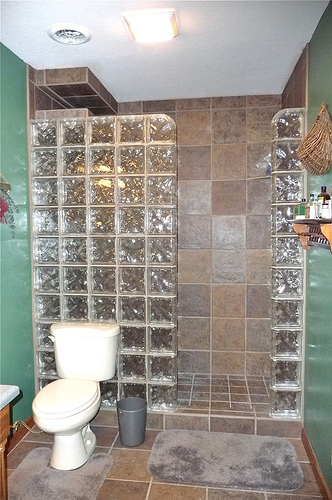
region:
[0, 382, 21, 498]
An edge of a wood framed granite topped bathroom sink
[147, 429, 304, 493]
A gray area rug used as a shower mat on the tiled floor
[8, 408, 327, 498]
Brown tiled bathroom floor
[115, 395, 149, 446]
Round green plastic garbage can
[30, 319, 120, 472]
White ceramic toilet against shower wall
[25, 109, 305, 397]
Glass block shower wall.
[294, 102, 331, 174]
Brown, woven wicker holder basket on right wall.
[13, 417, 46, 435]
Toilet water connection braided metal hose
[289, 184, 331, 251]
Wooden shelf on right wall loaded with toiletries.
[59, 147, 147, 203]
A yellow glow can be seen reflecting from or showing through the glass brick shower wall.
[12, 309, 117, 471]
White color western toilet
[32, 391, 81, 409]
Lid of the western toilet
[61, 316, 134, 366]
White color tank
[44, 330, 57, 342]
Handle of the tank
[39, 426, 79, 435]
Toilet bowl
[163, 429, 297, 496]
Grey color floor mate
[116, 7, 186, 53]
Ceiling light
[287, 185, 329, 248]
Wooden rack attached with wall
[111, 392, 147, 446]
Grey color dustbin near the western toilet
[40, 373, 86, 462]
this is a toilet sink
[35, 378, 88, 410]
this is the lid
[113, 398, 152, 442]
this is a container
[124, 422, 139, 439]
the container is made of plastic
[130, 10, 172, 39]
this is a light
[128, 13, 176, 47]
the light is on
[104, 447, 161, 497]
this is the floor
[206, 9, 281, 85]
this is the roof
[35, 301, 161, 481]
a bathroom toilet inside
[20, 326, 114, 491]
a bathroom toilet that is white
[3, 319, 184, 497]
a white toilet in the bathroom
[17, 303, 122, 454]
a toilet with lid down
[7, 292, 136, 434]
a toilet with seat down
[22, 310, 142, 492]
a white toilet with seat down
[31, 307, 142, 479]
a white toilet with lid down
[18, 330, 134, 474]
a bathroom toilet with white toilet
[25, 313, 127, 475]
A white porcelain toilet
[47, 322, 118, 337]
shiny white toilet tank lid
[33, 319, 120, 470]
clean white porcelain toilet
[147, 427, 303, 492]
fluffy grey bathroom rug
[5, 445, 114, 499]
fluffy grey toilet rug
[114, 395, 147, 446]
empty silver metal trashcan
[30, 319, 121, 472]
toilet in front of glass tile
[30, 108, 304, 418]
thick glass tile shower wall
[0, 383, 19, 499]
wood cabinet with white counter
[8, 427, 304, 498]
two matching grey rugs on bathroom floor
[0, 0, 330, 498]
bathroom with white ceiling and green walls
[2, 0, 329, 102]
A white ceiling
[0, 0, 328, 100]
Light in the ceiling is on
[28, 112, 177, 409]
Glass wall tile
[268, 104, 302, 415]
Glass wall tile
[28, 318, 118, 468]
Clean white toilet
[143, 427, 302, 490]
Fluffy gray rug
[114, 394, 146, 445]
Gray cylinder trash in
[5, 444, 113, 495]
Gray toilet rug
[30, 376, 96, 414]
White toilet lid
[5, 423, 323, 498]
Rugs on tile floor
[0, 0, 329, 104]
white vent on white ceiling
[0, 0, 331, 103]
bright light on white ceiling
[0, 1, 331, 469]
white ceiling above white toilet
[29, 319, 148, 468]
gray trashcan next to white toilet